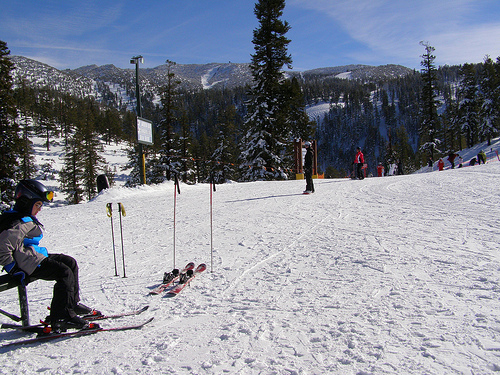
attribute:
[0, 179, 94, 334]
boy — looking, sitting, preparing, warm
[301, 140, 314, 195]
man — standing, alone, equiped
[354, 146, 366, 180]
woman — hanging, standing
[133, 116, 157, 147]
sigh — advertisement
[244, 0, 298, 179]
tree — snow, fat, tall, behind, snowy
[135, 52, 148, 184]
post — yellow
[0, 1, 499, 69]
sky — blue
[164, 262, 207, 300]
ski — alone, sitting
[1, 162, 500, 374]
slope — snowy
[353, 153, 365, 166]
jacket — red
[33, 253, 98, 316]
pants — black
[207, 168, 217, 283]
pole — upright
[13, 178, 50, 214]
helmet — black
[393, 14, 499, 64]
cloud — fluffy